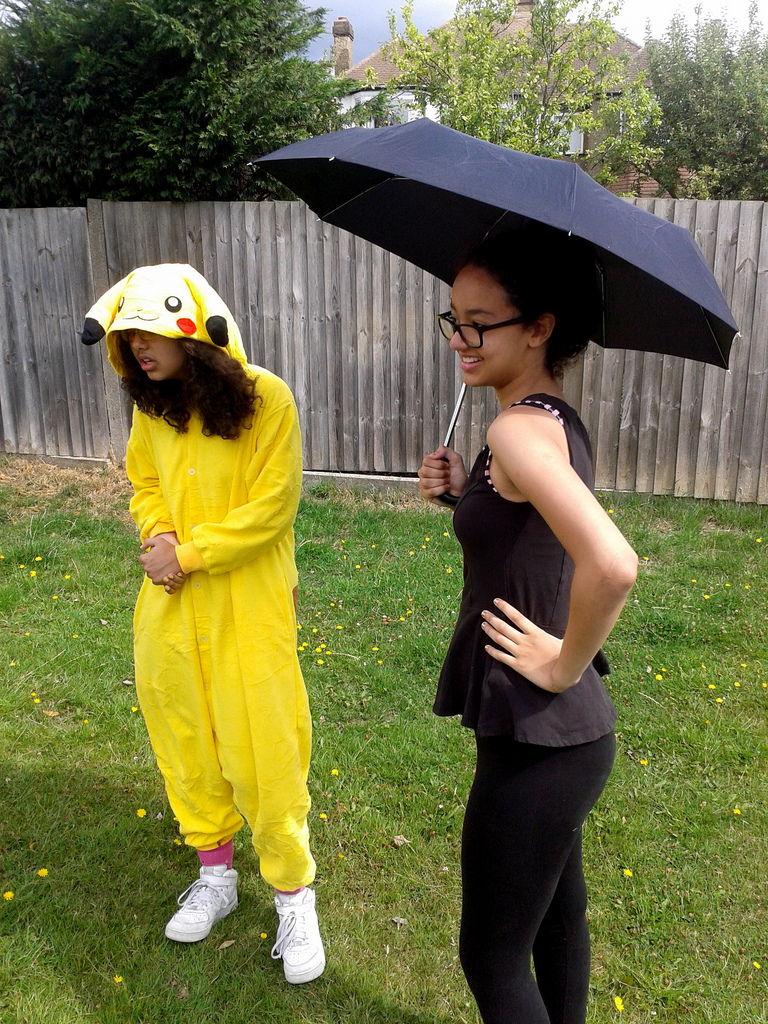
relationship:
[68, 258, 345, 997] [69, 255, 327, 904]
adult wearing pjs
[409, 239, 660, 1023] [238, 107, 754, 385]
girl holding umbrella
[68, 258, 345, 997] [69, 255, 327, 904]
adult in pjs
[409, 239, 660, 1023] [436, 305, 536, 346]
girl wearing glasses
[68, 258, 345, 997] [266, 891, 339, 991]
adult wearing shoes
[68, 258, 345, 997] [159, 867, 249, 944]
adult wearing shoes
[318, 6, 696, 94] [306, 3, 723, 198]
roof of house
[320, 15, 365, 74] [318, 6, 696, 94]
chimney on roof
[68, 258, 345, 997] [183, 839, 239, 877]
adult has socks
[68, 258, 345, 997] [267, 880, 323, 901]
adult wearing socks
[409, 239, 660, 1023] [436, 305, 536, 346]
girl has glasses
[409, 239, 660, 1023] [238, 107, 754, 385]
girl has umbrella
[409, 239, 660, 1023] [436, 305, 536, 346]
girl wears glasses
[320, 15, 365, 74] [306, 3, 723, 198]
chimney on house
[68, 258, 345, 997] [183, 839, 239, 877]
adult wearing socks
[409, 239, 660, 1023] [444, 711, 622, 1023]
girl wearing tights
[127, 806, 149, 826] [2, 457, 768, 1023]
flowers on grass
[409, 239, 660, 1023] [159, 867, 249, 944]
girl wearing shoes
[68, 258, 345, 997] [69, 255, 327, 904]
adult has pjs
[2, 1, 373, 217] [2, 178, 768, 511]
tree behind fence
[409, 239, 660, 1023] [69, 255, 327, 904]
girl wearing pjs